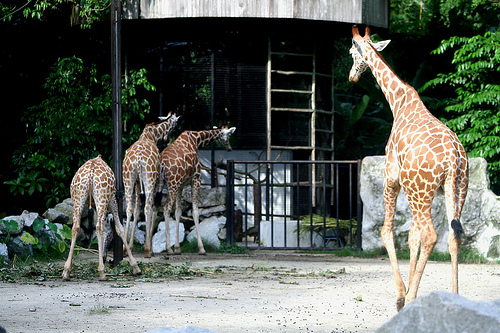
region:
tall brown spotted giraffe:
[332, 25, 488, 311]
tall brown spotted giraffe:
[109, 108, 191, 240]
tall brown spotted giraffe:
[55, 143, 161, 295]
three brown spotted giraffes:
[49, 78, 274, 284]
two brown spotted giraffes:
[112, 111, 227, 250]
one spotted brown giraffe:
[350, 22, 476, 321]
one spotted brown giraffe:
[162, 107, 244, 265]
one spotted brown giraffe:
[115, 109, 192, 238]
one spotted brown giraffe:
[55, 143, 131, 300]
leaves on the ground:
[22, 258, 250, 275]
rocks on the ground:
[171, 278, 347, 328]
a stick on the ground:
[152, 285, 271, 312]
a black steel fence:
[231, 153, 366, 248]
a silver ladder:
[268, 52, 320, 169]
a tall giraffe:
[346, 22, 476, 297]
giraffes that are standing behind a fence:
[35, 71, 473, 302]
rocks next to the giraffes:
[46, 181, 227, 243]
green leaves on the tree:
[412, 6, 498, 133]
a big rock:
[371, 296, 497, 328]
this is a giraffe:
[7, 133, 144, 294]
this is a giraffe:
[110, 100, 183, 267]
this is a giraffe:
[151, 108, 238, 270]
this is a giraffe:
[328, 24, 498, 324]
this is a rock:
[388, 282, 498, 332]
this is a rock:
[358, 143, 498, 271]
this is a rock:
[181, 210, 237, 263]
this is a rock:
[150, 215, 190, 261]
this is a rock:
[46, 197, 92, 239]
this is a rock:
[7, 205, 44, 248]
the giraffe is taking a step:
[342, 35, 472, 312]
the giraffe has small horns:
[349, 22, 370, 38]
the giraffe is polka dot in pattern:
[346, 27, 469, 314]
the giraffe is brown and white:
[348, 32, 468, 305]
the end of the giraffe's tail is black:
[451, 218, 463, 236]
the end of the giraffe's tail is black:
[87, 210, 93, 234]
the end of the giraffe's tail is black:
[138, 193, 147, 208]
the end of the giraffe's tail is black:
[155, 191, 163, 206]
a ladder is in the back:
[266, 52, 321, 216]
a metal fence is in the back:
[219, 153, 367, 253]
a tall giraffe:
[334, 28, 474, 307]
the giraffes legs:
[381, 220, 433, 290]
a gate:
[228, 159, 356, 246]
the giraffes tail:
[83, 177, 95, 213]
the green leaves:
[32, 103, 87, 149]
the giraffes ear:
[349, 34, 364, 53]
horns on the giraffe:
[349, 24, 369, 37]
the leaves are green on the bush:
[448, 53, 492, 120]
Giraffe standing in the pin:
[161, 120, 238, 256]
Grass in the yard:
[290, 209, 357, 246]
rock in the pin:
[45, 190, 70, 220]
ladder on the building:
[262, 42, 318, 196]